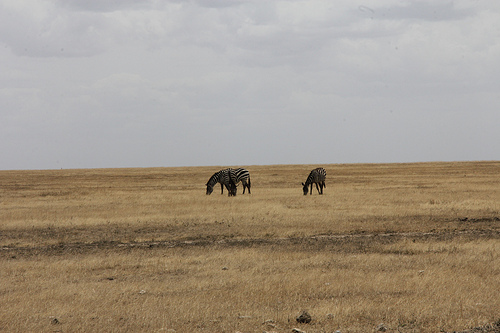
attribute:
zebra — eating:
[285, 160, 347, 215]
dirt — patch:
[9, 220, 498, 262]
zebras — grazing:
[206, 161, 331, 193]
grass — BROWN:
[1, 159, 496, 327]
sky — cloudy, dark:
[0, 0, 498, 172]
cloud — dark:
[230, 10, 323, 63]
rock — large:
[296, 310, 311, 323]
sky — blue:
[3, 6, 498, 153]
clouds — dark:
[0, 1, 499, 169]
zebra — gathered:
[204, 174, 238, 206]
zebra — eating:
[294, 165, 354, 205]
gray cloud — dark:
[350, 72, 401, 105]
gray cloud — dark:
[431, 35, 466, 71]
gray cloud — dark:
[207, 46, 259, 85]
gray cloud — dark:
[57, 74, 95, 110]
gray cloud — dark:
[118, 110, 155, 140]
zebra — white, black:
[298, 167, 330, 196]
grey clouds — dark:
[331, 11, 498, 111]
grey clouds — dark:
[4, 0, 184, 76]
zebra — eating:
[204, 167, 254, 197]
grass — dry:
[329, 260, 467, 319]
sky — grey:
[393, 29, 498, 101]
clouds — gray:
[113, 13, 332, 89]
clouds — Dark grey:
[82, 14, 372, 121]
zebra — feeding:
[190, 168, 260, 213]